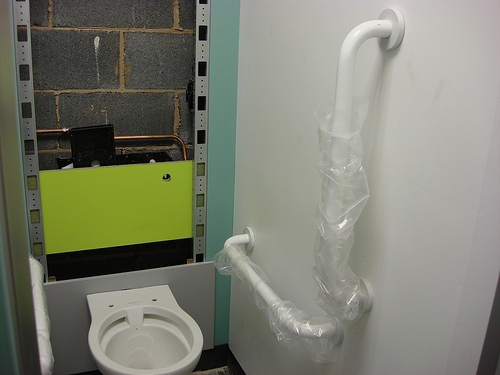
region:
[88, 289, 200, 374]
white toilet without a lid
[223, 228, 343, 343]
standing bar on the wall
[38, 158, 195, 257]
bright green panel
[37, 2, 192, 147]
old brick wall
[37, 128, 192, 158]
brass plumbing pipes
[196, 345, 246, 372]
black strips of floorboards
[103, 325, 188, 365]
water in the toilet bowl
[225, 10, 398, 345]
handicap standing bars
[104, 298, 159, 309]
holes for the toilet lid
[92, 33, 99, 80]
paint on the bricks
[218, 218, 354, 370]
Plastic on a handrail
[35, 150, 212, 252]
Green board on the wall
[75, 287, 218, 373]
Plastic toilet bowl against the wall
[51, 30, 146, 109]
Cement blocks behind the wall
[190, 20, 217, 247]
Metal beam on the wall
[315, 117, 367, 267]
Plastic on the hand guard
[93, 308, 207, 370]
White plastic toilet bowl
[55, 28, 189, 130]
Grey cement blocks on the wall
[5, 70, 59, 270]
Metal beams on the wall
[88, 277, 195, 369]
White toilet on the wall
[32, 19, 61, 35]
Light brown grout lines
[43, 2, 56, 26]
Light brown grout lines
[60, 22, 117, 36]
Light brown grout lines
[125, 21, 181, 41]
Light brown grout lines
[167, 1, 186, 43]
Light brown grout lines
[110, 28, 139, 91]
Light brown grout lines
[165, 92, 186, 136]
Light brown grout lines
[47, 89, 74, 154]
Light brown grout lines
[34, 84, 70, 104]
Light brown grout lines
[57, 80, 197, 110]
Light brown grout lines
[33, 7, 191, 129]
gray cinder block wall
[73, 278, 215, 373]
commode with no lid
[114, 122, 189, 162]
bent piece of copper pipe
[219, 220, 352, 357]
white handle with plastic cover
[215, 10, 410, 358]
two white handles on a wall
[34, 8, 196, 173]
cinderblocks and copper pipes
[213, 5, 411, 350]
safety grips on white wall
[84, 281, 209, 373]
toilet bowl without lid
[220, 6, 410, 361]
vertical and horizontal safety handles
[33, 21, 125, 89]
cinder block with white stain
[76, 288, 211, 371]
curves and holes in back of white toilet bowl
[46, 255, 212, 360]
gray panel in back of toilet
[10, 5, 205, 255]
green panel between vertical bars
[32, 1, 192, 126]
gray cinder blocks forming wall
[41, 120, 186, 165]
small black panel in front of curved copper pipes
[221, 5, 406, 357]
plastic bags over white grab bars on wall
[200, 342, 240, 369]
black band on corner of floor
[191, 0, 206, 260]
rectangular cutouts between three dots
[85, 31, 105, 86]
white oval and drip on wall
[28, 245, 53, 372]
toilet panel in plastic bag leaning on side